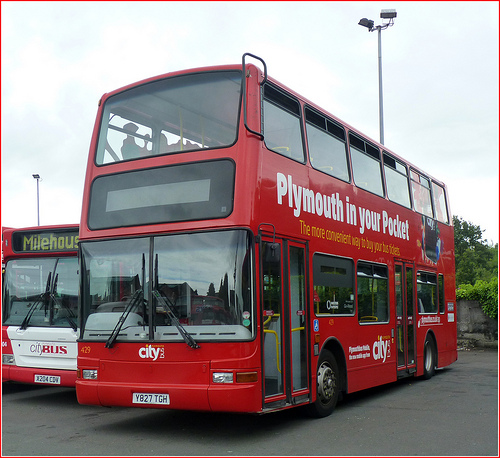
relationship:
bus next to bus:
[74, 54, 455, 415] [2, 224, 81, 388]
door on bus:
[258, 229, 288, 411] [74, 54, 455, 415]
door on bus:
[391, 258, 406, 370] [74, 54, 455, 415]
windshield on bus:
[79, 236, 150, 343] [74, 54, 455, 415]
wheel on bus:
[309, 352, 339, 417] [74, 54, 455, 415]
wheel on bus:
[423, 331, 439, 377] [74, 54, 455, 415]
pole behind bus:
[359, 11, 397, 147] [74, 54, 455, 415]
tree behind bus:
[449, 216, 498, 318] [74, 54, 455, 415]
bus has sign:
[2, 224, 81, 388] [10, 227, 81, 252]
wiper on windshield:
[153, 256, 204, 352] [149, 225, 251, 340]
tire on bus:
[423, 331, 439, 377] [74, 54, 455, 415]